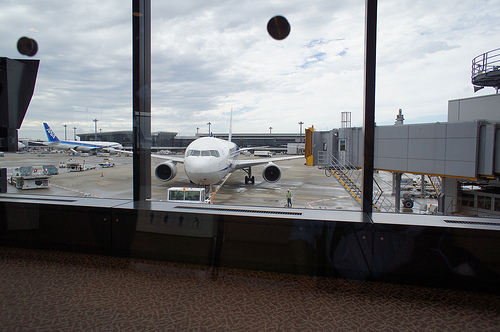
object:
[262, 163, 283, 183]
engine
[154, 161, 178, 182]
engine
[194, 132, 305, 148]
building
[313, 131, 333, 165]
door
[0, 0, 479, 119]
air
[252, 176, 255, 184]
wheel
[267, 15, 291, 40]
circle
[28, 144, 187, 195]
runway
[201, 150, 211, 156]
windows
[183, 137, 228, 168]
cockpit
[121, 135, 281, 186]
an airplane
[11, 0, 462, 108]
clouds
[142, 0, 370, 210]
window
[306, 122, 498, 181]
loading bridge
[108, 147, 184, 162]
wing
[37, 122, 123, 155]
plane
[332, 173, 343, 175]
steps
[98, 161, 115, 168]
truck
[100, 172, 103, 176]
cone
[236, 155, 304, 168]
left wing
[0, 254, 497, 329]
carpet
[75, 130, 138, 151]
building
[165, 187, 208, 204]
taxis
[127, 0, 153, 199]
pole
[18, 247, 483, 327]
floor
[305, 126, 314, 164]
belt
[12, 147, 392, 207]
tarmac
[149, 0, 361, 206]
glass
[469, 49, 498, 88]
balcony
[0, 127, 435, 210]
airport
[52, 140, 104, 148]
stripe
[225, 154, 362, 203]
runway